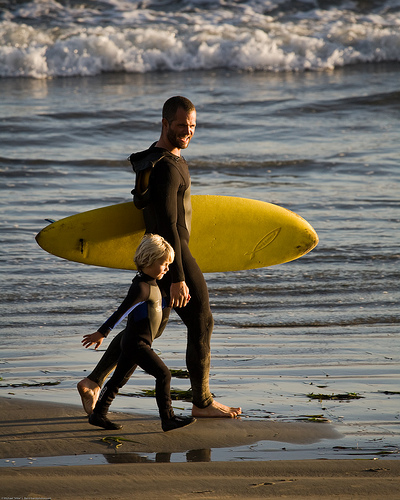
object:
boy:
[79, 229, 199, 432]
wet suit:
[94, 276, 175, 421]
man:
[77, 95, 244, 419]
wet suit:
[87, 141, 218, 410]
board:
[34, 194, 321, 276]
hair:
[161, 95, 196, 120]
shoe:
[161, 411, 199, 431]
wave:
[0, 0, 400, 82]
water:
[0, 0, 400, 473]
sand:
[0, 391, 399, 498]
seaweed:
[302, 386, 364, 402]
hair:
[133, 229, 178, 265]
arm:
[98, 284, 147, 335]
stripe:
[108, 322, 114, 332]